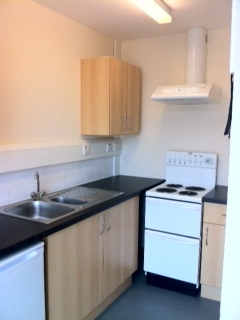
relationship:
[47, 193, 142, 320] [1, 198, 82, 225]
cabinets are under sink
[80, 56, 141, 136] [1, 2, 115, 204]
cabinets hang on wall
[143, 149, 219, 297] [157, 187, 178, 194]
stove has electric burner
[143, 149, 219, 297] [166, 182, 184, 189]
stove has electric burner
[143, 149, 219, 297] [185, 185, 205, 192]
stove has electric burner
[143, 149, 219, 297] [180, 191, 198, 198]
stove has electric burner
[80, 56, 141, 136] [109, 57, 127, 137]
cabinet has door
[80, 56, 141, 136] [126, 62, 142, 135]
cabinet has door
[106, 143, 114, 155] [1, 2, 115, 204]
electrical outlet on wall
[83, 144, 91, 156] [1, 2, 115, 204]
electrical outlet on wall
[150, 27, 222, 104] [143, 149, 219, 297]
electric vent above stove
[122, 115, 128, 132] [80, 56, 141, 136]
handle on cabinet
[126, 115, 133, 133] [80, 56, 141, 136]
handle on cabinet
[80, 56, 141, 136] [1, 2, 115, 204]
cabinets mounted on wall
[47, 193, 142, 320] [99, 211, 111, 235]
cabinets have handles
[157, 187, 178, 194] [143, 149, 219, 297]
electric burner on stove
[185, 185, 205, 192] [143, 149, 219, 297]
electric burner on stove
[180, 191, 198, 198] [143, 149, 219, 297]
electric burner on stove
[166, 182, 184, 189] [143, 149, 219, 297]
electric burner on stove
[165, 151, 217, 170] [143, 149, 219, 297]
panel of buttons on stove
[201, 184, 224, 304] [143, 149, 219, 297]
cabinet to right of stove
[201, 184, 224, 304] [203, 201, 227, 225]
cabinet has drawer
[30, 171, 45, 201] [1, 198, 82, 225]
faucet on sink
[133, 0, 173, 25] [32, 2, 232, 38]
light on ceiling